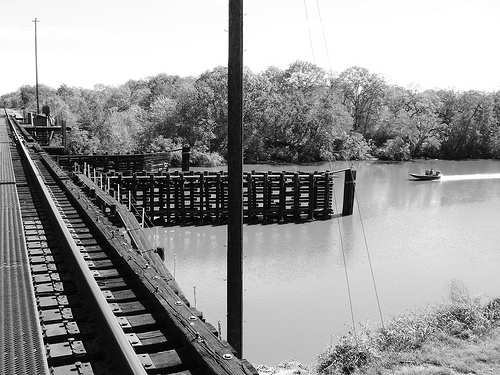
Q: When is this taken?
A: During the day.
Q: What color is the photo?
A: Black and white.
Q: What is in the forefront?
A: Tracks.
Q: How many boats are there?
A: One.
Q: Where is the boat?
A: In the water.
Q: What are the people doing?
A: Boating.